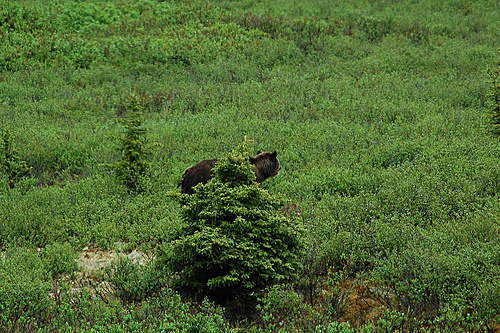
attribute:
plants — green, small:
[0, 0, 499, 332]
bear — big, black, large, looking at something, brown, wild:
[176, 149, 282, 197]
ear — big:
[271, 150, 278, 158]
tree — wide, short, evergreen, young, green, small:
[160, 133, 308, 299]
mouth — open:
[275, 167, 281, 175]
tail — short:
[177, 172, 186, 189]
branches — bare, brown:
[302, 251, 404, 313]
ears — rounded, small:
[255, 147, 279, 155]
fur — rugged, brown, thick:
[175, 148, 282, 198]